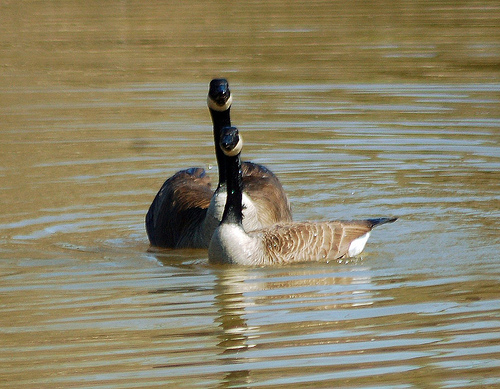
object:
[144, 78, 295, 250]
bird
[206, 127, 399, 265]
bird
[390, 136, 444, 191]
wall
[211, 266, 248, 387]
goose reflection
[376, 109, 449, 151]
ground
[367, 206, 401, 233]
woman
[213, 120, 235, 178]
neck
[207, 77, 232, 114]
head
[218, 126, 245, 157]
head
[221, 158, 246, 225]
neck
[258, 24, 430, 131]
water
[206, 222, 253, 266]
chest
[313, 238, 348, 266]
wing feathers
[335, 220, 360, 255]
edge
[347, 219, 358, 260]
edge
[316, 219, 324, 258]
edge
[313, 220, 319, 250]
edge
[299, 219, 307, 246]
edge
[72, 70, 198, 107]
reflection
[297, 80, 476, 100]
reflection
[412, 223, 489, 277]
reflection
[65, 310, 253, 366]
reflection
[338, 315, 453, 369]
reflection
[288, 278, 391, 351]
ripples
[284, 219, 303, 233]
feathers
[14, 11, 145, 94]
water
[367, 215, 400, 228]
tail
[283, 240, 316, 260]
feathers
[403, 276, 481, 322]
water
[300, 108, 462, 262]
water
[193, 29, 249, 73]
water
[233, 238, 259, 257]
feathers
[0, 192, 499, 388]
ridges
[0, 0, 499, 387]
shore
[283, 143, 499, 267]
ripple